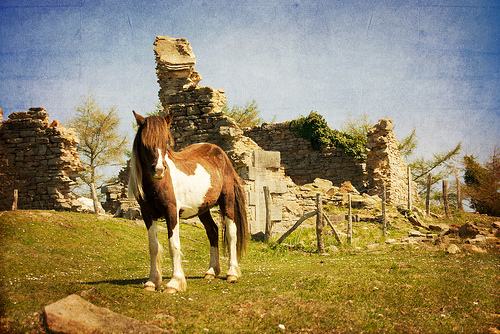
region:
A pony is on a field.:
[86, 120, 283, 317]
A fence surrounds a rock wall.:
[253, 164, 490, 245]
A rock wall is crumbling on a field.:
[20, 118, 117, 233]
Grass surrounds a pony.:
[128, 261, 306, 316]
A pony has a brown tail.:
[209, 143, 266, 259]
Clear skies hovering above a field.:
[258, 45, 460, 169]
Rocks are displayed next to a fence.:
[397, 220, 481, 270]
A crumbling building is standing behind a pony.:
[171, 59, 380, 216]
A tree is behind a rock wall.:
[70, 105, 115, 219]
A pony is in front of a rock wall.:
[120, 107, 289, 292]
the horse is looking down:
[99, 95, 216, 214]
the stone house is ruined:
[11, 26, 411, 267]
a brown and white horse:
[127, 108, 329, 300]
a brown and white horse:
[74, 89, 271, 285]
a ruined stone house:
[106, 11, 401, 295]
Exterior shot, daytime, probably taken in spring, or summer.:
[5, 10, 498, 329]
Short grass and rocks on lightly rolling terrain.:
[35, 217, 471, 327]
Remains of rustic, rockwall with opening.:
[2, 104, 84, 212]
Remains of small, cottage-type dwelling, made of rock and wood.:
[132, 33, 398, 233]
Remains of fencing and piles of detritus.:
[268, 180, 488, 270]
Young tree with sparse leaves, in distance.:
[74, 102, 109, 219]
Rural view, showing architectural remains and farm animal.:
[3, 8, 496, 333]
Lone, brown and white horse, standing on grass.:
[127, 87, 266, 293]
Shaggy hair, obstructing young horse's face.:
[139, 116, 180, 173]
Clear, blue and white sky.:
[39, 18, 446, 116]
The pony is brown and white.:
[124, 108, 249, 300]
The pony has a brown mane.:
[133, 105, 173, 180]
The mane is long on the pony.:
[128, 108, 178, 178]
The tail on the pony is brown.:
[224, 163, 251, 259]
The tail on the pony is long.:
[223, 171, 252, 262]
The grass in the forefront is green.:
[230, 288, 320, 330]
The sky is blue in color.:
[369, 3, 498, 64]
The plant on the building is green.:
[290, 113, 367, 157]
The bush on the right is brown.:
[464, 151, 498, 214]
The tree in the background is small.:
[68, 94, 126, 216]